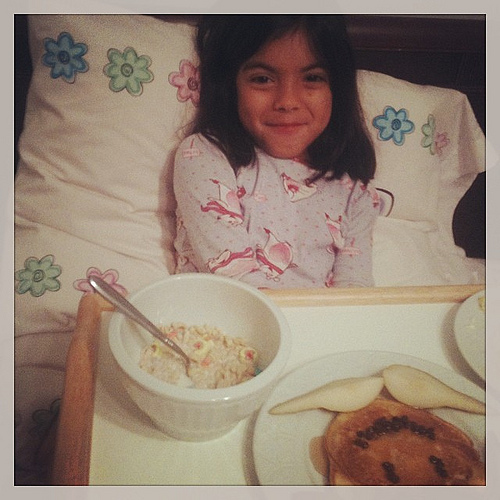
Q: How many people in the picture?
A: One.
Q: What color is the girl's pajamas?
A: Pink.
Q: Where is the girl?
A: In the bed.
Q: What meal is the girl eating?
A: Breakfast.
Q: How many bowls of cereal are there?
A: One.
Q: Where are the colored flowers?
A: On the pillow.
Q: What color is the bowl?
A: White.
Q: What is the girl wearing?
A: Pajamas.